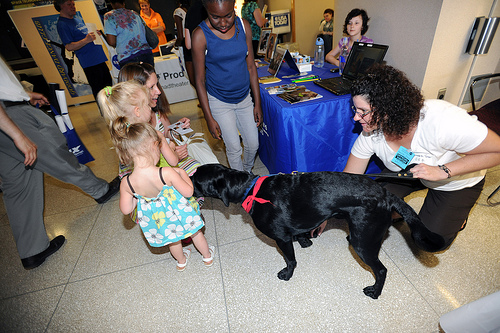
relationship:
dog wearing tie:
[189, 162, 449, 303] [239, 170, 273, 217]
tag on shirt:
[390, 145, 416, 172] [344, 99, 491, 191]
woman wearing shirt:
[335, 67, 499, 254] [344, 99, 491, 191]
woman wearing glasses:
[335, 67, 499, 254] [347, 103, 381, 118]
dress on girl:
[126, 165, 209, 250] [108, 116, 217, 269]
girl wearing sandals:
[108, 116, 217, 269] [172, 244, 217, 271]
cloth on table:
[251, 58, 387, 178] [255, 59, 356, 109]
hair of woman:
[349, 63, 424, 144] [335, 67, 499, 254]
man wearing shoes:
[21, 172, 122, 270] [19, 170, 124, 270]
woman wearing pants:
[335, 67, 499, 254] [373, 171, 489, 254]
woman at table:
[321, 6, 379, 68] [255, 59, 356, 109]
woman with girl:
[111, 59, 199, 148] [108, 116, 216, 272]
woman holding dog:
[335, 67, 499, 254] [189, 162, 449, 303]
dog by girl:
[189, 162, 449, 303] [108, 116, 216, 272]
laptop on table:
[313, 41, 387, 99] [255, 59, 356, 109]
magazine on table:
[282, 84, 324, 106] [255, 59, 356, 109]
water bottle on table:
[310, 37, 326, 69] [255, 59, 356, 109]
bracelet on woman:
[435, 163, 455, 182] [335, 67, 499, 254]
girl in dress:
[108, 116, 217, 269] [126, 165, 209, 250]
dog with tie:
[189, 162, 449, 303] [239, 170, 273, 217]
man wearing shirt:
[52, 0, 117, 117] [53, 13, 110, 72]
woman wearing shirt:
[135, 0, 172, 58] [140, 8, 174, 55]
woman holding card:
[111, 59, 199, 148] [167, 121, 196, 137]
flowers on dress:
[149, 206, 180, 229] [126, 165, 209, 250]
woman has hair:
[335, 67, 499, 254] [349, 63, 424, 144]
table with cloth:
[255, 59, 356, 109] [251, 58, 387, 178]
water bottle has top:
[310, 37, 326, 69] [313, 35, 325, 47]